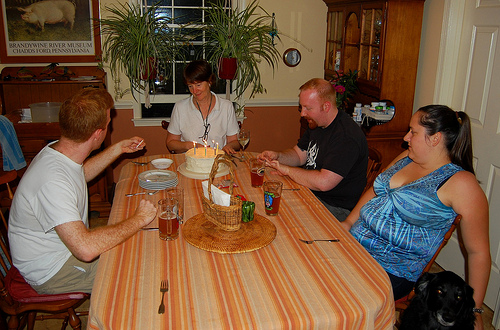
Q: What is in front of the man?
A: A glass.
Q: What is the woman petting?
A: A dog.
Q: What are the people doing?
A: Sitting.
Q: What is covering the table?
A: A tablecloth.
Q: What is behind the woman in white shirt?
A: A window.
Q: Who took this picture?
A: A friend.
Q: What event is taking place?
A: Birthday.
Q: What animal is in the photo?
A: A dog.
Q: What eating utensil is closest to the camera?
A: A fork.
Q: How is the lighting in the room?
A: Dim.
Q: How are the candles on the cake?
A: Lit.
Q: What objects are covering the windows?
A: Plants.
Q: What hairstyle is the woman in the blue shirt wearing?
A: Ponytail.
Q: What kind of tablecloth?
A: Orange.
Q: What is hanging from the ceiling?
A: Plants.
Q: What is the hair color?
A: Red.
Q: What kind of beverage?
A: Iced tea.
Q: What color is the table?
A: Orange and white.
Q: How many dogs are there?
A: One.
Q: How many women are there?
A: Two.